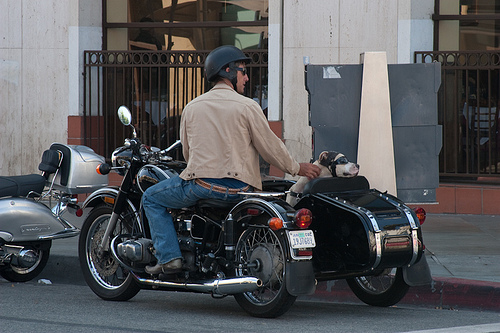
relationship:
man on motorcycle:
[107, 34, 326, 276] [0, 135, 117, 290]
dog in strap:
[269, 143, 373, 231] [278, 173, 316, 201]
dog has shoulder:
[269, 143, 373, 231] [296, 163, 327, 194]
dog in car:
[269, 143, 373, 231] [258, 138, 401, 298]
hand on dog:
[297, 144, 327, 172] [269, 143, 373, 231]